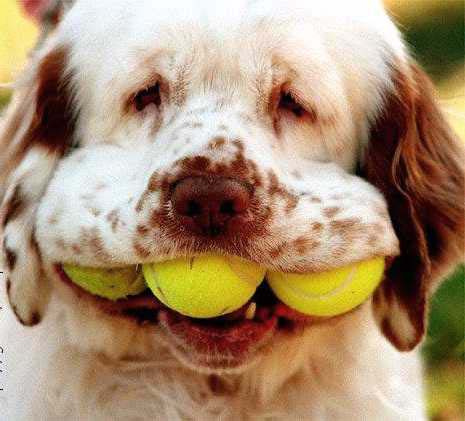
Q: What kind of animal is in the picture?
A: Dog.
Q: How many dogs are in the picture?
A: One.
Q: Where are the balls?
A: The dog's mouth.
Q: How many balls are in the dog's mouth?
A: 3.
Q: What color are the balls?
A: Yellow.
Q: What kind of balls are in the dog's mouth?
A: Tennis balls.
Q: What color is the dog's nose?
A: Brown.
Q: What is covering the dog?
A: Fur.